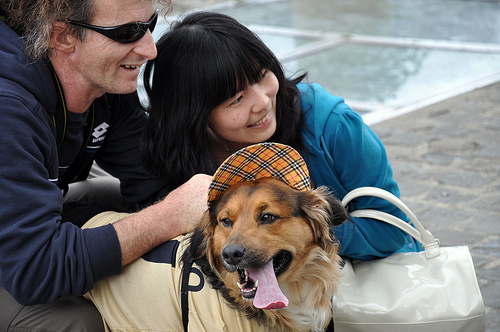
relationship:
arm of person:
[54, 169, 225, 281] [28, 7, 197, 277]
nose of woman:
[250, 83, 268, 111] [147, 8, 427, 260]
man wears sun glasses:
[3, 0, 198, 297] [60, 6, 160, 45]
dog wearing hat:
[77, 177, 350, 330] [206, 143, 313, 223]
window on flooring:
[279, 34, 499, 124] [403, 96, 500, 250]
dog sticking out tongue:
[192, 177, 349, 329] [246, 258, 290, 310]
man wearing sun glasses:
[3, 0, 213, 332] [60, 6, 160, 42]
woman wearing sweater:
[147, 8, 427, 260] [276, 79, 411, 248]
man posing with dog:
[3, 0, 213, 332] [77, 177, 350, 330]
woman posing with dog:
[147, 8, 427, 260] [77, 177, 350, 330]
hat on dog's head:
[187, 139, 334, 201] [214, 170, 345, 309]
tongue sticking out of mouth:
[254, 257, 286, 317] [227, 242, 294, 292]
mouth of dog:
[227, 242, 294, 292] [77, 177, 350, 330]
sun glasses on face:
[60, 6, 160, 45] [68, 0, 160, 95]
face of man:
[68, 0, 160, 95] [3, 0, 213, 332]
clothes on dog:
[70, 199, 292, 330] [77, 177, 350, 330]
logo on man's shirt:
[87, 121, 113, 148] [0, 20, 168, 300]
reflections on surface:
[294, 9, 454, 89] [333, 15, 495, 118]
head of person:
[139, 7, 297, 161] [132, 16, 389, 223]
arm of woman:
[302, 79, 408, 261] [147, 8, 427, 260]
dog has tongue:
[77, 177, 350, 330] [244, 257, 288, 309]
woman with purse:
[148, 22, 338, 174] [331, 192, 481, 329]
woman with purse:
[147, 8, 427, 260] [248, 157, 483, 329]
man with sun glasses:
[3, 0, 213, 332] [60, 6, 160, 45]